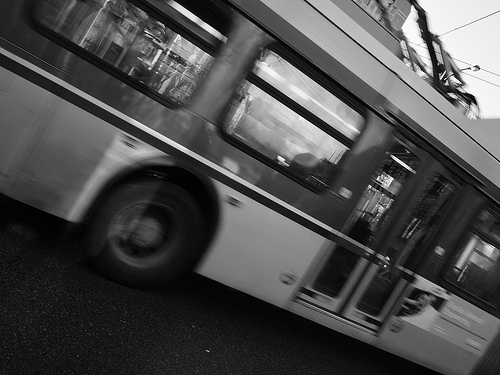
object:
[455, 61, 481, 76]
lamp post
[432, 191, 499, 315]
window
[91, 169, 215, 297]
bus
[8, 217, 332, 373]
road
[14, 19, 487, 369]
picture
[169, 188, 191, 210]
black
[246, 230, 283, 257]
white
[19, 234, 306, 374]
asphalt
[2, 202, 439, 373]
street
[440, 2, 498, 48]
sky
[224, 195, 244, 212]
light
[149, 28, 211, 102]
window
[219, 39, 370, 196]
window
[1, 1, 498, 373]
bus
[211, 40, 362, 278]
side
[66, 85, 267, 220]
reflection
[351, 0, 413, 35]
building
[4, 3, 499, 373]
passenger bus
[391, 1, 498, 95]
wires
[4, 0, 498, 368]
photo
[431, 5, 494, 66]
lines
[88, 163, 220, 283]
wheel